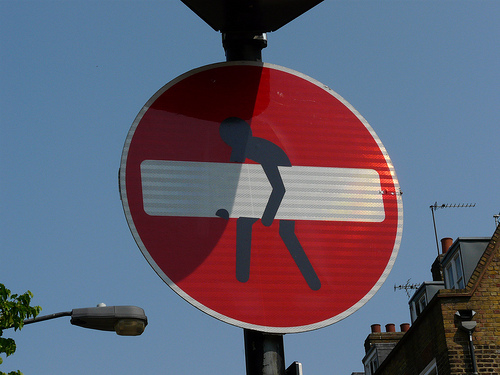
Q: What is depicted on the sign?
A: A human carrying a white bar.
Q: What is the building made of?
A: Bricks.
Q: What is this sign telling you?
A: Surfer crossing.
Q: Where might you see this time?
A: At the beach.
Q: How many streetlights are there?
A: 1.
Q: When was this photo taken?
A: In the afternoon.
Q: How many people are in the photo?
A: None.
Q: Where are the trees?
A: In the lower left-hand corner of the photo.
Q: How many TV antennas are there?
A: 2.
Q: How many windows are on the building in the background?
A: 6.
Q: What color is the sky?
A: Blue.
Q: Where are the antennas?
A: Roof tops.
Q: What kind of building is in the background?
A: Brick.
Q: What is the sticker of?
A: A man.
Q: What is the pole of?
A: Red sign.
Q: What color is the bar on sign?
A: White.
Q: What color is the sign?
A: Red and white.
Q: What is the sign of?
A: Man carrying surfboard.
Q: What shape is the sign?
A: Circle.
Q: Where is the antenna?
A: Top of building.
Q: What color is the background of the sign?
A: Red.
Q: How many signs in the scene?
A: 1.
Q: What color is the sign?
A: Red with black and white.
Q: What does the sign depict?
A: A person carrying a long object.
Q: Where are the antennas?
A: On the roofs.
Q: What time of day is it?
A: Daytime.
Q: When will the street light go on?
A: At dusk.